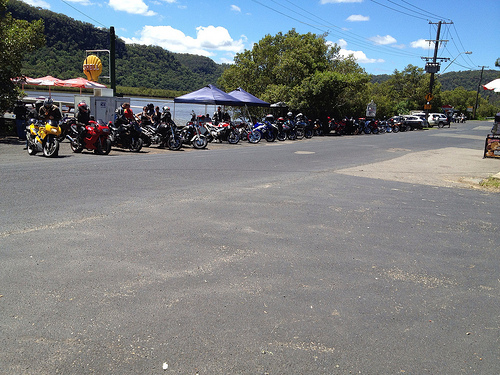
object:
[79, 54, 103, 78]
sign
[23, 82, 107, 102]
gas station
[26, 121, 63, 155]
motorcycle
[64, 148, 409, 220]
street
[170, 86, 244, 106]
tarp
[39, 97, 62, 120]
rider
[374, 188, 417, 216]
asphalt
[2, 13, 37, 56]
tree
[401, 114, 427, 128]
vehicle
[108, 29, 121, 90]
pole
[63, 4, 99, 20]
power line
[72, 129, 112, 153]
motorcycle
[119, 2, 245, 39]
sky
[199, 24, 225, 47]
cloud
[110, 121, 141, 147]
motorcycle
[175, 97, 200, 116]
lake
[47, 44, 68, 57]
foliage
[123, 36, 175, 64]
hill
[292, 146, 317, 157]
sewage drain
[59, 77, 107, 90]
umbrella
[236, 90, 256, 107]
tarp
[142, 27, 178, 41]
cloud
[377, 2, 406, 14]
power line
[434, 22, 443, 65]
pole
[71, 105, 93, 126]
rider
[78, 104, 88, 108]
helmet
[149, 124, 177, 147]
motorcycle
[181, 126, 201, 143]
motorcycle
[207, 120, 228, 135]
motorcycle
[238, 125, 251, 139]
motorcycle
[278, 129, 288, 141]
motorcycle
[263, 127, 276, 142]
motorcycle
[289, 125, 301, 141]
motorcycle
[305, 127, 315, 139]
motorcycle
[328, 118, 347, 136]
motorcycle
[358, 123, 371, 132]
motorcycle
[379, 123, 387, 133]
motorcycle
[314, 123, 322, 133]
motorcycle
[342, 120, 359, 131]
motorcycle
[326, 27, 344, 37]
power line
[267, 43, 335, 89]
tree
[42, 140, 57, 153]
wheel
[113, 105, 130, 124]
rider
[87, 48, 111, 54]
pole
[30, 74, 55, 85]
umbrella